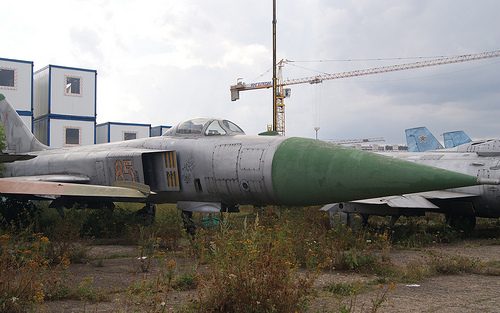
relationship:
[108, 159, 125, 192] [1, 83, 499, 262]
number 8 on plane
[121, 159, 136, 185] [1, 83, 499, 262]
number 5 on plane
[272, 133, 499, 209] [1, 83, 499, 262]
nose of plane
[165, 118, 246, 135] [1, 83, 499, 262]
cockpit of plane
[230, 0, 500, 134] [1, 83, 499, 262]
crane behind plane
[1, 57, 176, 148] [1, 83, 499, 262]
rectangle boxes behind plane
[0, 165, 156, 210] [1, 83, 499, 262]
wing of plane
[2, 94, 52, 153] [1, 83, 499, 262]
tail of plane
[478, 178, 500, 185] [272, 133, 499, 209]
tip of nose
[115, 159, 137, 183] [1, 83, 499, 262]
number 85 on plane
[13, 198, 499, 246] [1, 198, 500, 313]
grass on ground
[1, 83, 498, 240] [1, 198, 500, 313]
plane on ground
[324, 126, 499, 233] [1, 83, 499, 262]
jets behind plane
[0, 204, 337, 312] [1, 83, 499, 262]
weeds under plane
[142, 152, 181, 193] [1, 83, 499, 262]
opening on plane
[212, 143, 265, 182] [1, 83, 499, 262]
rivets on plane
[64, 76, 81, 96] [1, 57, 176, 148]
window on rectangle boxes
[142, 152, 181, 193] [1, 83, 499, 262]
opening on side of plane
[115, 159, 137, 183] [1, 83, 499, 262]
number 85 on side of plane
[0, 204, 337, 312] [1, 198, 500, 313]
weeds on ground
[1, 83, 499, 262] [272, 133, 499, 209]
plane has green nose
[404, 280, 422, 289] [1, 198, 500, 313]
paper on ground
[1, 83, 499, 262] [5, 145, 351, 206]
plane has side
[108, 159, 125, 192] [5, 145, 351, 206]
number 8 on side